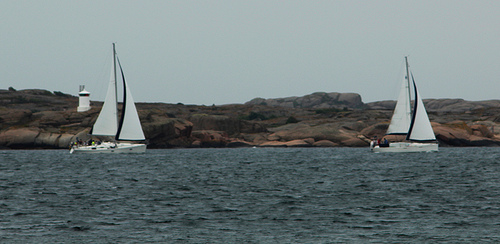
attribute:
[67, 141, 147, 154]
boat — white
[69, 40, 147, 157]
sailboat — white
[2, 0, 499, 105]
sky — blue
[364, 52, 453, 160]
sailboat — white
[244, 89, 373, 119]
mountain — rock, large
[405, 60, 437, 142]
sail — blue, white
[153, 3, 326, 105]
sky — blue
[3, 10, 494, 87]
clouds — white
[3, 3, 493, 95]
sky — blue, gray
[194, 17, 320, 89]
clouds — white, gray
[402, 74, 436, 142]
sail — white, blue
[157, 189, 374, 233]
water — large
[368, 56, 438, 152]
boat — blue, white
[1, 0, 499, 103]
clouds — white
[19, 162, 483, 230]
water — blue